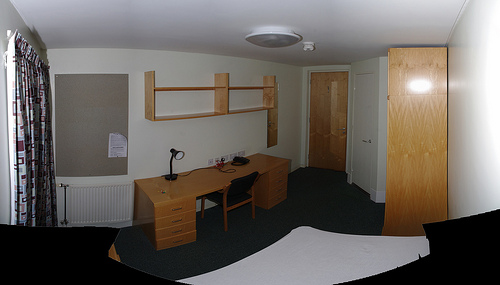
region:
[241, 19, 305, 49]
A white ceiling light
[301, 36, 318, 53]
A smoke detector on the ceiling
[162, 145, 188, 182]
A black computer lamp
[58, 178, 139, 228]
A white wall radiator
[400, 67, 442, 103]
A reflection of light on the wood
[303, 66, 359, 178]
A closed wooden door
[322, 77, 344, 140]
A window on the door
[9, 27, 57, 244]
Decorative gray drapes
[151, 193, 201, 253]
4 desk drawers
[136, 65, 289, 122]
Wooden shelving on the wall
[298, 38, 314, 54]
White fire alarm on ceiling.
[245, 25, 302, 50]
White large light on ceiling.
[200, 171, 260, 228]
Black and wooden chair at desk.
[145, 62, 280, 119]
Light wooden book shelf on wall.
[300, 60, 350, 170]
Closed light brown wooden door.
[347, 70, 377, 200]
Closed painted white door.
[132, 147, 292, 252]
Light brown wooden desk.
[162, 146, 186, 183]
Black lamp on desk.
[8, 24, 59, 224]
Long blue, purple and pink curtains.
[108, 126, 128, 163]
White piece of paper hanging on wall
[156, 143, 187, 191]
a black desk lamp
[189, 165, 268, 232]
a black desk chair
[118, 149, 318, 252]
a brown wooden desk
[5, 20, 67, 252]
a grey and red curtain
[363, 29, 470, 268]
a brown wooden bookcase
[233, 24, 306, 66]
a white ceiling light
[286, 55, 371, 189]
a brown wooden door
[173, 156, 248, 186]
this is a cable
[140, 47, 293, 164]
a brown wooden shelf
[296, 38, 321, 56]
a white fire alarm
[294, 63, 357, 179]
The door is closed.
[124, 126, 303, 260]
The desk is wood.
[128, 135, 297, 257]
A lamp is on the desk.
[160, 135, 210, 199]
The lamp is off.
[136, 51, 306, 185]
Shelves are hanging on the wall.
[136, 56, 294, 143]
The shelves are wood.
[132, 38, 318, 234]
The wall is white.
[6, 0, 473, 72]
The ceiling is white.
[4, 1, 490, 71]
The ceiling light is off.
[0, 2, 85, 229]
The curtains are closed.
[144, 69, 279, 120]
shelves attached to the wall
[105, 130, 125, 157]
a piece of paper on a cork board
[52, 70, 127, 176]
a cork board on the wall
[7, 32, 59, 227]
floor length curtains over a window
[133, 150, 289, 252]
a tan wooden desk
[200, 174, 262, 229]
a chair in front of the desk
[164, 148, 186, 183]
a black table lamp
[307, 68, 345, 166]
the door to the bedroom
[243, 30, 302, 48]
a round ceiling light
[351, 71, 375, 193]
a white closet door